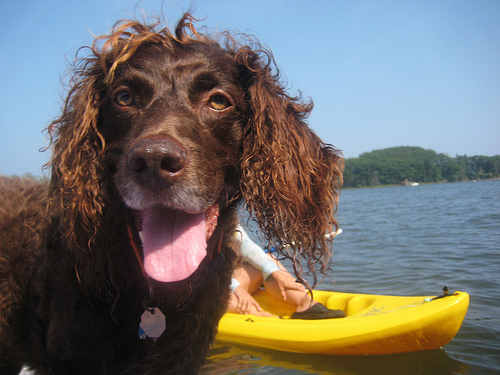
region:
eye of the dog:
[201, 88, 243, 112]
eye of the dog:
[107, 83, 156, 114]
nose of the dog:
[117, 138, 194, 175]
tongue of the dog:
[104, 208, 224, 303]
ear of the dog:
[235, 84, 337, 246]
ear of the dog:
[45, 90, 107, 217]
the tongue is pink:
[141, 230, 193, 260]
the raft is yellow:
[361, 323, 411, 345]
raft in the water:
[394, 282, 472, 355]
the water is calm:
[393, 198, 469, 238]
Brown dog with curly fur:
[0, 16, 344, 373]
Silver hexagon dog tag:
[135, 302, 170, 341]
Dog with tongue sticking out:
[0, 11, 347, 374]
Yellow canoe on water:
[209, 213, 469, 356]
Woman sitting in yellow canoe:
[222, 216, 346, 324]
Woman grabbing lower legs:
[228, 222, 347, 322]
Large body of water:
[192, 177, 498, 374]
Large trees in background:
[330, 145, 498, 187]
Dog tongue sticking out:
[140, 203, 207, 282]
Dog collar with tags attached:
[115, 211, 231, 344]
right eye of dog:
[194, 89, 236, 121]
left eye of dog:
[107, 83, 139, 114]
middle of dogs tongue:
[158, 233, 184, 246]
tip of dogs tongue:
[158, 263, 191, 279]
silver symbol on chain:
[129, 307, 174, 339]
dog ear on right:
[272, 147, 329, 239]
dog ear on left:
[53, 208, 114, 278]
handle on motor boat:
[437, 282, 453, 297]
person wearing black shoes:
[283, 302, 348, 321]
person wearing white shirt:
[247, 252, 260, 263]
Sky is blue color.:
[319, 34, 460, 119]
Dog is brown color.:
[35, 44, 298, 372]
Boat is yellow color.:
[246, 257, 480, 374]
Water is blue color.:
[366, 203, 495, 288]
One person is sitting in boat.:
[221, 218, 311, 335]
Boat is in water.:
[253, 253, 460, 365]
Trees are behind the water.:
[336, 129, 498, 202]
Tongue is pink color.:
[138, 201, 200, 280]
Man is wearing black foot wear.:
[285, 287, 362, 342]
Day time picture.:
[20, 19, 483, 354]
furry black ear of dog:
[235, 55, 350, 251]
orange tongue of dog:
[137, 215, 209, 282]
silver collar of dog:
[133, 305, 173, 333]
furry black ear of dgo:
[32, 99, 98, 231]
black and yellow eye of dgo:
[203, 94, 231, 113]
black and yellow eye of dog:
[103, 86, 145, 109]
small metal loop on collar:
[139, 305, 155, 318]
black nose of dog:
[113, 127, 190, 188]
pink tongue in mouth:
[126, 213, 209, 289]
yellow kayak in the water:
[304, 272, 483, 337]